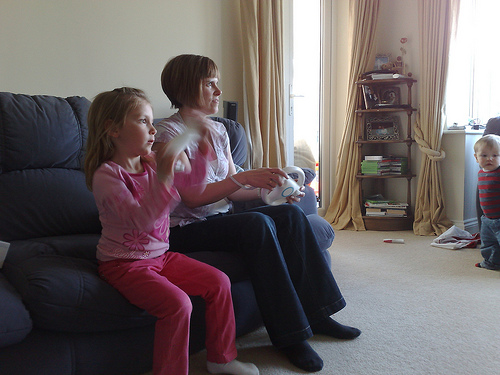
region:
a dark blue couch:
[5, 94, 331, 365]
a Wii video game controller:
[263, 164, 303, 207]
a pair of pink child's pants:
[97, 250, 233, 369]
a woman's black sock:
[277, 342, 325, 372]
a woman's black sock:
[312, 313, 359, 340]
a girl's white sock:
[210, 358, 260, 373]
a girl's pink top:
[91, 157, 206, 259]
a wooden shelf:
[350, 70, 415, 233]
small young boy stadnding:
[467, 133, 498, 270]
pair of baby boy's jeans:
[480, 215, 498, 269]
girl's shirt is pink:
[48, 155, 180, 265]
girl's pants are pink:
[98, 245, 255, 363]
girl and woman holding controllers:
[61, 10, 330, 237]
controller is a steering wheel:
[243, 137, 314, 214]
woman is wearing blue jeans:
[188, 191, 423, 364]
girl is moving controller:
[72, 62, 207, 175]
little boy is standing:
[460, 123, 499, 287]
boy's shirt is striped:
[464, 164, 499, 214]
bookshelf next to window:
[337, 45, 434, 252]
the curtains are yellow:
[246, 1, 454, 233]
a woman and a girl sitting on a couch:
[85, 53, 360, 374]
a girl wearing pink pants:
[100, 255, 237, 374]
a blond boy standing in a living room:
[473, 136, 498, 270]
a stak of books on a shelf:
[358, 153, 409, 173]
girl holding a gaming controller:
[156, 130, 195, 181]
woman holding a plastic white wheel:
[248, 161, 305, 207]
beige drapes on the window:
[242, 0, 460, 232]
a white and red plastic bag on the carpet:
[432, 225, 482, 248]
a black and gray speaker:
[222, 100, 239, 121]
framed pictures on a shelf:
[362, 83, 400, 108]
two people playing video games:
[72, 48, 369, 374]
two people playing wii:
[45, 40, 383, 373]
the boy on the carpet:
[458, 128, 499, 269]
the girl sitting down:
[80, 70, 254, 373]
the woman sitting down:
[133, 45, 365, 367]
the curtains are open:
[237, 5, 397, 230]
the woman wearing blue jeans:
[173, 208, 370, 339]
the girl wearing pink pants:
[101, 255, 243, 366]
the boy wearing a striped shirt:
[479, 167, 498, 219]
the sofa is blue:
[3, 98, 365, 369]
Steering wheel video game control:
[261, 167, 307, 206]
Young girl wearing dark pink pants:
[88, 84, 237, 371]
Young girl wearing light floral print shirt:
[89, 86, 239, 371]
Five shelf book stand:
[355, 70, 418, 230]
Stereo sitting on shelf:
[363, 112, 406, 145]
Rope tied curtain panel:
[413, 1, 449, 236]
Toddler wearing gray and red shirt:
[475, 132, 498, 274]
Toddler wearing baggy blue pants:
[472, 133, 499, 272]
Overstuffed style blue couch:
[1, 87, 336, 364]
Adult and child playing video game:
[89, 52, 308, 236]